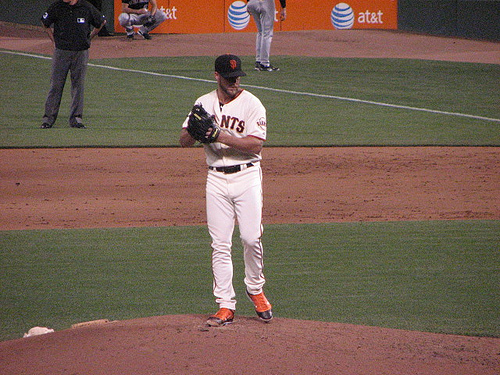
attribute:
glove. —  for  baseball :
[176, 98, 226, 148]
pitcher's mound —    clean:
[118, 343, 347, 374]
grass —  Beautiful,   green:
[311, 224, 471, 311]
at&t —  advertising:
[320, 7, 431, 33]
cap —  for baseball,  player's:
[214, 49, 252, 77]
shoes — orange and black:
[200, 296, 282, 329]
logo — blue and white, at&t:
[331, 1, 361, 31]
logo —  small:
[229, 59, 236, 69]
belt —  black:
[201, 160, 261, 179]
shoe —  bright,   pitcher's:
[246, 289, 277, 322]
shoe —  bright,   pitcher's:
[207, 307, 237, 329]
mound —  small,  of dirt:
[38, 283, 483, 374]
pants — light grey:
[242, 0, 273, 66]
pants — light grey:
[117, 8, 167, 39]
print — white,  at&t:
[353, 10, 386, 24]